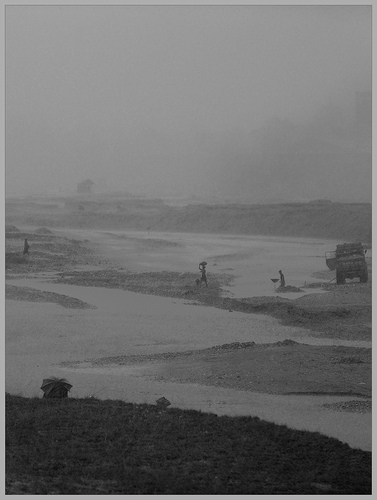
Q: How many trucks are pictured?
A: One.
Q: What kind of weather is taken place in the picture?
A: Rain.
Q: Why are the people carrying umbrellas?
A: Raining.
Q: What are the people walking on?
A: Gravel.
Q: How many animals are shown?
A: Zero.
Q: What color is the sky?
A: Grey.